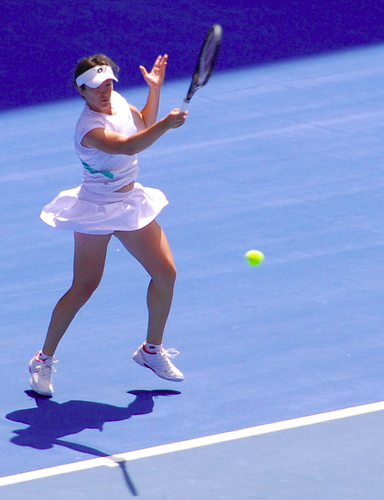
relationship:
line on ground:
[0, 400, 382, 488] [2, 45, 382, 498]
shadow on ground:
[4, 389, 182, 498] [2, 45, 382, 498]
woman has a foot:
[27, 51, 186, 399] [28, 350, 55, 401]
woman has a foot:
[27, 51, 186, 399] [131, 342, 184, 383]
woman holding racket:
[27, 51, 186, 399] [178, 22, 224, 115]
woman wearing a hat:
[27, 51, 186, 399] [73, 64, 119, 90]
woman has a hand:
[27, 51, 186, 399] [164, 107, 189, 131]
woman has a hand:
[27, 51, 186, 399] [136, 53, 170, 91]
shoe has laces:
[131, 342, 184, 383] [155, 344, 181, 370]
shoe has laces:
[28, 350, 55, 401] [34, 360, 55, 387]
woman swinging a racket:
[27, 51, 186, 399] [178, 22, 224, 115]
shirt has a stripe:
[70, 89, 135, 193] [78, 157, 113, 183]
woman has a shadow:
[27, 51, 186, 399] [4, 389, 182, 498]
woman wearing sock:
[27, 51, 186, 399] [36, 348, 56, 367]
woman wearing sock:
[27, 51, 186, 399] [144, 341, 166, 353]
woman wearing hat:
[27, 51, 186, 399] [73, 64, 119, 90]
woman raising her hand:
[27, 51, 186, 399] [164, 107, 189, 131]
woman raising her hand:
[27, 51, 186, 399] [136, 53, 170, 91]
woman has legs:
[27, 51, 186, 399] [40, 229, 114, 357]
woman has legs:
[27, 51, 186, 399] [112, 219, 176, 348]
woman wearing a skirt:
[27, 51, 186, 399] [38, 184, 169, 235]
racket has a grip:
[178, 22, 224, 115] [177, 97, 191, 116]